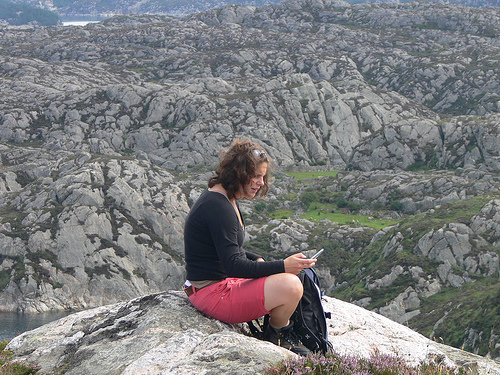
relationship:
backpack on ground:
[246, 266, 334, 358] [333, 302, 498, 373]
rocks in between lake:
[2, 0, 499, 316] [7, 313, 43, 325]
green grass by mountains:
[270, 164, 397, 227] [1, 0, 498, 373]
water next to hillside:
[16, 297, 103, 327] [39, 121, 140, 271]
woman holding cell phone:
[182, 138, 318, 357] [310, 248, 325, 259]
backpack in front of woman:
[271, 254, 341, 360] [162, 124, 377, 346]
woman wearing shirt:
[182, 138, 318, 357] [177, 187, 260, 272]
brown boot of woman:
[259, 316, 319, 357] [182, 138, 318, 357]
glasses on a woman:
[252, 146, 269, 160] [182, 138, 318, 357]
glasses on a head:
[252, 146, 269, 160] [210, 140, 267, 196]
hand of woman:
[284, 252, 316, 273] [182, 138, 318, 357]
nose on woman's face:
[256, 178, 265, 190] [230, 154, 273, 197]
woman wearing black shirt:
[129, 143, 371, 358] [164, 197, 374, 321]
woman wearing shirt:
[182, 138, 318, 357] [183, 183, 283, 281]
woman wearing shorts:
[182, 138, 318, 357] [181, 277, 270, 324]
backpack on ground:
[246, 266, 334, 358] [0, 279, 498, 374]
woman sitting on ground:
[182, 138, 318, 357] [1, 292, 498, 373]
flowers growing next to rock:
[274, 349, 477, 374] [3, 280, 498, 372]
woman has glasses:
[182, 138, 318, 357] [249, 149, 266, 159]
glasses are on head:
[249, 149, 266, 159] [225, 142, 267, 199]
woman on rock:
[182, 138, 318, 357] [3, 280, 498, 372]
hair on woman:
[202, 140, 269, 198] [182, 138, 318, 357]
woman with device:
[182, 138, 318, 357] [308, 245, 325, 259]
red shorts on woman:
[185, 277, 266, 321] [183, 128, 303, 343]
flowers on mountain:
[270, 345, 468, 374] [1, 288, 498, 374]